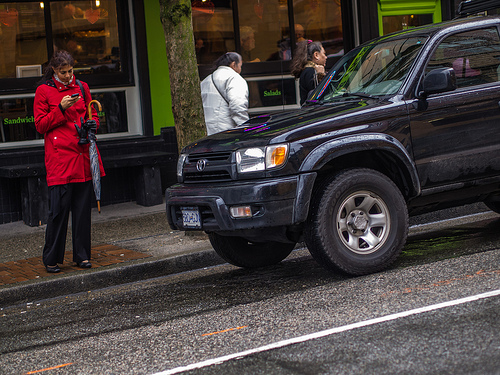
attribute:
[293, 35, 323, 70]
hair — long, brown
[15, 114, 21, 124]
letter — green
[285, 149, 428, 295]
tire — Black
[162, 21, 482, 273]
suv — black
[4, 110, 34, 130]
letters — green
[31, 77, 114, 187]
jacket — red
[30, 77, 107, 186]
coat — red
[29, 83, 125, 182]
shirt — black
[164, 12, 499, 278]
toyota suv — Black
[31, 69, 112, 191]
coat — red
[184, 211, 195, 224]
letter — green